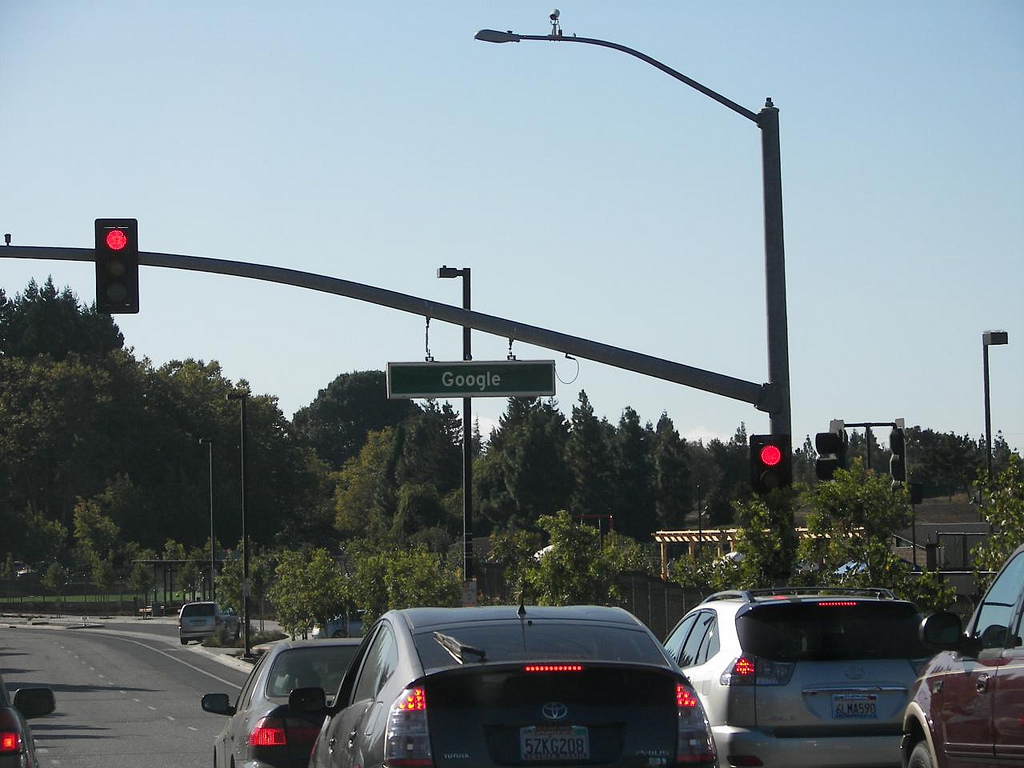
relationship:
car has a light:
[351, 585, 715, 763] [386, 669, 439, 728]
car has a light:
[172, 606, 341, 754] [244, 710, 294, 762]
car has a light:
[304, 597, 728, 767] [393, 667, 450, 756]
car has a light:
[172, 606, 341, 754] [239, 699, 306, 758]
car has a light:
[304, 597, 728, 767] [379, 669, 436, 760]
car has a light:
[304, 597, 728, 767] [673, 725, 715, 764]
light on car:
[509, 641, 628, 693] [319, 585, 676, 763]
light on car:
[397, 688, 430, 712] [338, 572, 702, 745]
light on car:
[652, 663, 717, 720] [328, 585, 718, 754]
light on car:
[716, 656, 764, 682] [701, 548, 931, 763]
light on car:
[205, 600, 232, 633] [155, 578, 262, 665]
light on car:
[177, 617, 193, 648] [163, 581, 246, 646]